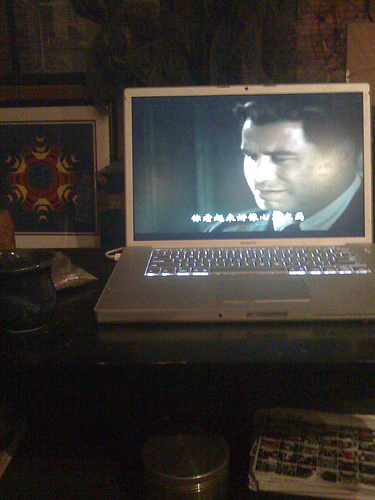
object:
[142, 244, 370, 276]
keyboard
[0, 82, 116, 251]
graphic print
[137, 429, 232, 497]
disc case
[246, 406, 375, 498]
book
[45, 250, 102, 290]
bag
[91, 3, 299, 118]
drapes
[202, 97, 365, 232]
man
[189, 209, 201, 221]
letters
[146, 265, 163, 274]
key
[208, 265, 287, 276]
key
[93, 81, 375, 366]
laptop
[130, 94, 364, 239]
screen